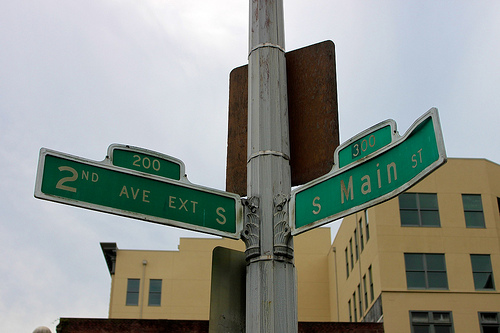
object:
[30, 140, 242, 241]
sign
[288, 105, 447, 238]
sign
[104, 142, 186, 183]
sign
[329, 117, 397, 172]
sign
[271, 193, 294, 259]
brackets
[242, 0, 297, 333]
street pole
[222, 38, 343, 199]
street sign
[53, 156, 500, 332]
building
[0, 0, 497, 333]
sky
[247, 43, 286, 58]
top bracket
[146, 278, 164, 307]
windows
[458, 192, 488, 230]
window